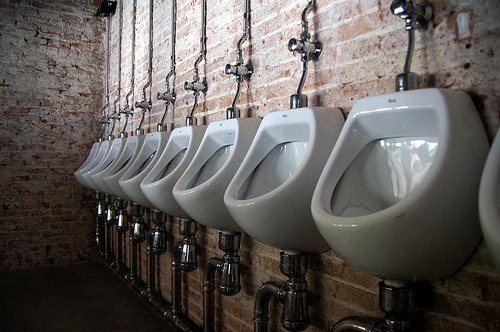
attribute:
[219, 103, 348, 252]
urinal — white, small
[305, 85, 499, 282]
urinal — white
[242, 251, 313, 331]
pipe — silver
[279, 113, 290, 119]
words — gray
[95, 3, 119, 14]
object — black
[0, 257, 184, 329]
floor — brown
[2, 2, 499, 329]
photo — detailed, striking, picturesque